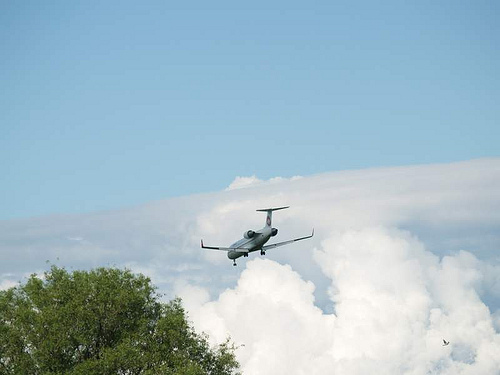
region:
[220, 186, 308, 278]
gray plane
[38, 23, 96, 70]
white clouds in blue sky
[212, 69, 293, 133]
white clouds in blue sky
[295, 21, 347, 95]
white clouds in blue sky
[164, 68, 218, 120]
white clouds in blue sky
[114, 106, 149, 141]
white clouds in blue sky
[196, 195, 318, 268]
large plane in blue sky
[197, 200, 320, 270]
rear view of commercial lane in blue sky with white clouds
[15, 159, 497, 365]
white clouds in blue sky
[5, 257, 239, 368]
green bushy tree in foreground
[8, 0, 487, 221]
clear blue sunny sky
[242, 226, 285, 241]
two engines on large silver plane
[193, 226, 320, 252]
two long wings on silver plane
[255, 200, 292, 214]
silver tail on large plane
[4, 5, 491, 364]
outdoor sunny plane flying in blue sky scene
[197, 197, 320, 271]
commercial airliner flying above clouds during day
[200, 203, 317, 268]
Flying plane in the air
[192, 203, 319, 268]
Commercial plane flying between clouds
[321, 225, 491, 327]
White clouds in the blue sky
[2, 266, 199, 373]
Green top of a tall tree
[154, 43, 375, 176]
Clear light blue sky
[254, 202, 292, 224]
Commercial airplane back tail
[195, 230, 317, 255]
Airplane right and left wings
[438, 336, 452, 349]
Black bird flying among the clouds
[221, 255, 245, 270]
Commercial aircraft under wheels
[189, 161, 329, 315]
airplane in the sky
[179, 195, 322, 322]
airplane in the sky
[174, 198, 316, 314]
airplane in the sky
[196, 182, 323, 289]
airplane in the sky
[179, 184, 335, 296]
airplane in the sky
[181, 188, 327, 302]
airplane in the sky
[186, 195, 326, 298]
airplane in the sky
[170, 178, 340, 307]
airplane in the sky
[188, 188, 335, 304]
airplane in the sky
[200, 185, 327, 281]
airplane in the sky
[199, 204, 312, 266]
a plane flying low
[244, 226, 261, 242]
the canopy of the plane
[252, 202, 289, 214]
the tail wing of the plane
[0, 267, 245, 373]
tree top near the plane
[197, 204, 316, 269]
a low flying aircraft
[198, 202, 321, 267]
a plane with landing gear extended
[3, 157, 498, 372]
a cloud bank in the lower sky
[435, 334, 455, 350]
a bird flying on the lower right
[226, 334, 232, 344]
a couple of leaves on a tree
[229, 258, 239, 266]
front landing gear of the plane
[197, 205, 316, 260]
plane flying in the air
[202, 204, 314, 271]
the plane is gray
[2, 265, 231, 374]
leaves on tree are green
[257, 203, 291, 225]
the tail of the airplane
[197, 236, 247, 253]
the airplane's wing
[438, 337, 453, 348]
the bird is flying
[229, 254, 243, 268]
airplane's landing gear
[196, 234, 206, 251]
winglet on an airplane wing